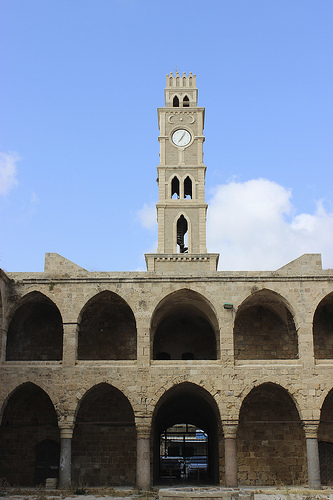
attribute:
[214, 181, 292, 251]
white clouds — fluffy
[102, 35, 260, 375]
building — brick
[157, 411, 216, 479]
gate — metal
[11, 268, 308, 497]
building — beige